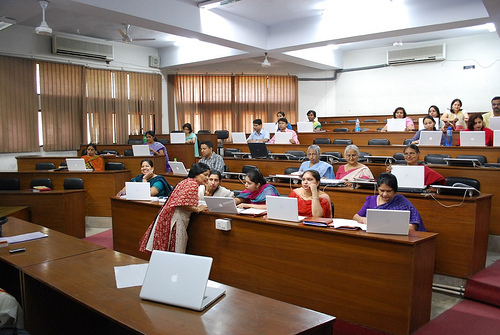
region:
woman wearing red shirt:
[305, 201, 312, 209]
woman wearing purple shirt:
[391, 199, 405, 209]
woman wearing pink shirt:
[338, 167, 346, 177]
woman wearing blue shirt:
[311, 165, 323, 170]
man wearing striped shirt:
[209, 156, 219, 166]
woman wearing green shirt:
[154, 184, 164, 188]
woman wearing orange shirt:
[94, 162, 101, 167]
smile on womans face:
[138, 167, 152, 174]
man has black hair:
[203, 141, 210, 146]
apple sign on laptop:
[425, 134, 437, 144]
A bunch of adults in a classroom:
[76, 93, 498, 257]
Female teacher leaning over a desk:
[135, 160, 213, 255]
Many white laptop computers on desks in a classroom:
[66, 115, 497, 311]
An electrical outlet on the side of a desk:
[211, 217, 232, 232]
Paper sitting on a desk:
[2, 230, 49, 245]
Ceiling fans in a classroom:
[18, 9, 295, 78]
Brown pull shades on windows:
[3, 50, 305, 157]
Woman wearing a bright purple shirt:
[355, 171, 423, 234]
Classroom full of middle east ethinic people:
[80, 96, 499, 266]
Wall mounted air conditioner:
[385, 42, 447, 63]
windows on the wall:
[5, 58, 305, 123]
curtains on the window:
[183, 76, 289, 124]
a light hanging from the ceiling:
[261, 57, 272, 67]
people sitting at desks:
[56, 120, 488, 267]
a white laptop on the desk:
[137, 251, 225, 308]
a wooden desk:
[113, 190, 421, 310]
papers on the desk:
[9, 226, 51, 241]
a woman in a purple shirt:
[363, 173, 423, 217]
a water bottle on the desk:
[354, 118, 361, 128]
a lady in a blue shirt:
[129, 163, 169, 190]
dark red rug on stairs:
[453, 305, 496, 327]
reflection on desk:
[38, 260, 53, 275]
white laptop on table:
[133, 234, 226, 320]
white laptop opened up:
[263, 193, 304, 221]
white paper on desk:
[111, 264, 141, 290]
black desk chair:
[60, 176, 85, 188]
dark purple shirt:
[365, 193, 411, 211]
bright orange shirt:
[83, 153, 105, 170]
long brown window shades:
[89, 64, 116, 151]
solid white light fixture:
[257, 52, 272, 70]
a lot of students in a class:
[221, 105, 425, 302]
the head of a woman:
[195, 166, 210, 181]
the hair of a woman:
[182, 162, 199, 179]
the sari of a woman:
[157, 179, 201, 211]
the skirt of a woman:
[147, 206, 207, 257]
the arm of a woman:
[305, 186, 325, 218]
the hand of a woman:
[300, 183, 321, 193]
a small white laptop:
[137, 243, 227, 323]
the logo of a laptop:
[168, 266, 192, 294]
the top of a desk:
[34, 239, 108, 306]